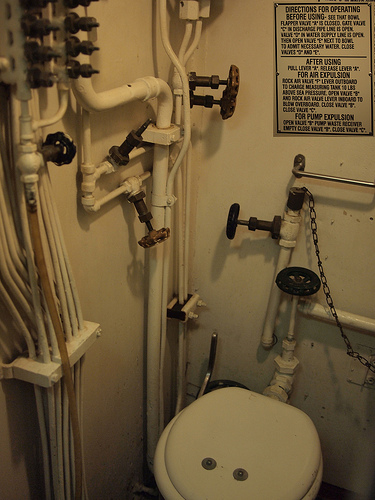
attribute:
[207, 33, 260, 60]
wall — white, dirty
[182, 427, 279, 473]
lid — white, down, closed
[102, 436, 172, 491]
toilet — white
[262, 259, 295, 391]
pipes — several, white, many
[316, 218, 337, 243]
wires — some, white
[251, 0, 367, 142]
sign — white, hanging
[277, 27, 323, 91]
letters — black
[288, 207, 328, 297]
chain — black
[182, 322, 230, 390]
handle — solver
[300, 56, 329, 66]
word — after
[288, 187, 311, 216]
turn off — black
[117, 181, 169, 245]
knobs — attached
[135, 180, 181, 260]
pipe — white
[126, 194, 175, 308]
pipe lines — many